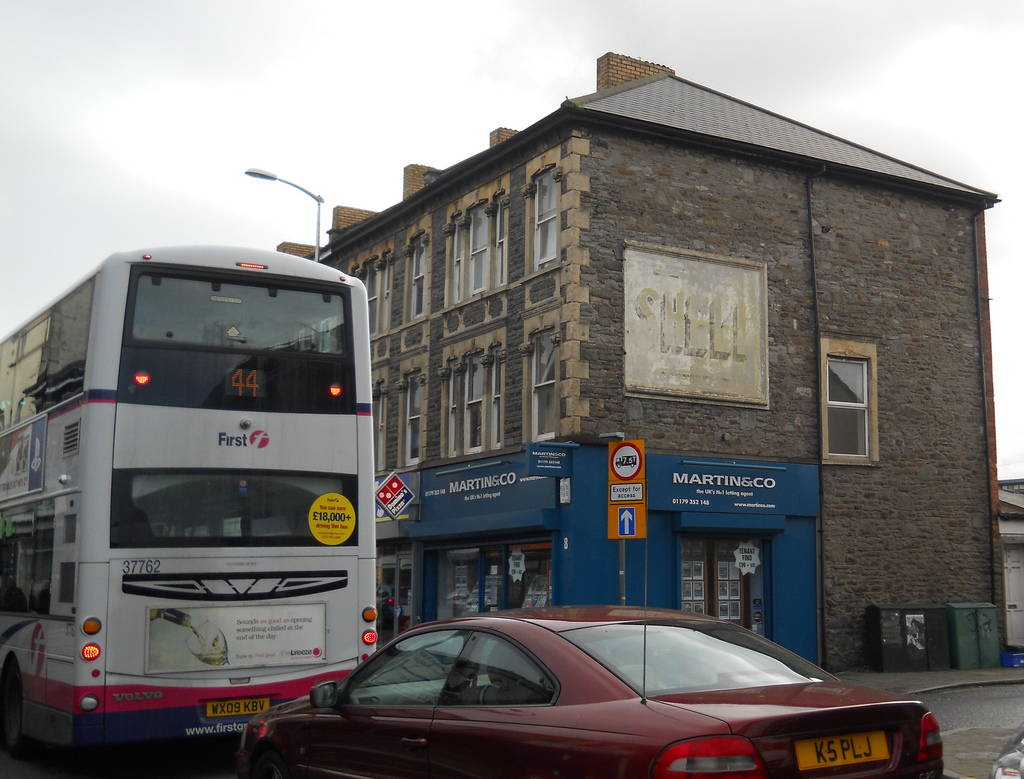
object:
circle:
[305, 489, 360, 548]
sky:
[43, 18, 393, 191]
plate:
[201, 695, 280, 717]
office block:
[219, 52, 996, 722]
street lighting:
[216, 149, 337, 248]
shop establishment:
[414, 454, 825, 695]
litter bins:
[976, 599, 1001, 673]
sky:
[13, 4, 1018, 479]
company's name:
[194, 425, 248, 449]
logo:
[251, 429, 269, 449]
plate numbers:
[825, 733, 840, 777]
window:
[791, 325, 901, 483]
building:
[317, 70, 1005, 682]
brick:
[844, 549, 878, 571]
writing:
[651, 467, 790, 520]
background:
[51, 2, 978, 527]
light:
[84, 641, 108, 660]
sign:
[151, 611, 242, 666]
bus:
[7, 242, 376, 742]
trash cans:
[852, 594, 1019, 699]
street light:
[232, 160, 274, 192]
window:
[540, 612, 835, 695]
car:
[243, 610, 946, 773]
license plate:
[793, 727, 891, 768]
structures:
[863, 576, 1002, 687]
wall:
[808, 472, 1010, 687]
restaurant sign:
[371, 465, 414, 526]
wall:
[383, 209, 566, 607]